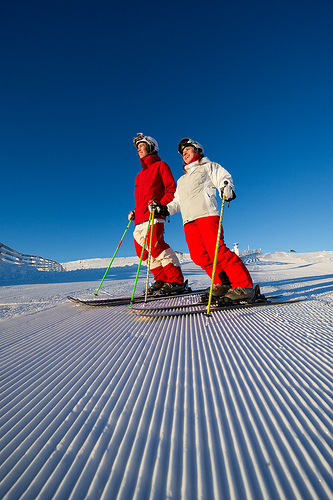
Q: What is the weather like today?
A: It is clear.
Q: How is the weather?
A: It is clear.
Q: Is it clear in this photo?
A: Yes, it is clear.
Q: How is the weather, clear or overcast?
A: It is clear.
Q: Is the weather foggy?
A: No, it is clear.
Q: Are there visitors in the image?
A: No, there are no visitors.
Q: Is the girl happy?
A: Yes, the girl is happy.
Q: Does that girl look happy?
A: Yes, the girl is happy.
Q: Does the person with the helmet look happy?
A: Yes, the girl is happy.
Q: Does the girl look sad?
A: No, the girl is happy.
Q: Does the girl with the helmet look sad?
A: No, the girl is happy.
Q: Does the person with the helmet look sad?
A: No, the girl is happy.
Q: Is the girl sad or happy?
A: The girl is happy.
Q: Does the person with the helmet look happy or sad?
A: The girl is happy.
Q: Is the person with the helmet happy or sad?
A: The girl is happy.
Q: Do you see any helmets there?
A: Yes, there is a helmet.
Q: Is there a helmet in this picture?
A: Yes, there is a helmet.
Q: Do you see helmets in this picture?
A: Yes, there is a helmet.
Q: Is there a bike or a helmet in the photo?
A: Yes, there is a helmet.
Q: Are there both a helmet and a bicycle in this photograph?
A: No, there is a helmet but no bicycles.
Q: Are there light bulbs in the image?
A: No, there are no light bulbs.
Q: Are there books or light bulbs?
A: No, there are no light bulbs or books.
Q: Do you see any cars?
A: No, there are no cars.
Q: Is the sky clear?
A: Yes, the sky is clear.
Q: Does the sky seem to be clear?
A: Yes, the sky is clear.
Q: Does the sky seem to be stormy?
A: No, the sky is clear.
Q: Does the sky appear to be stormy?
A: No, the sky is clear.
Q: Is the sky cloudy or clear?
A: The sky is clear.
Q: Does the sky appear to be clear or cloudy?
A: The sky is clear.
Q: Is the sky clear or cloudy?
A: The sky is clear.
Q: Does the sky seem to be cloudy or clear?
A: The sky is clear.